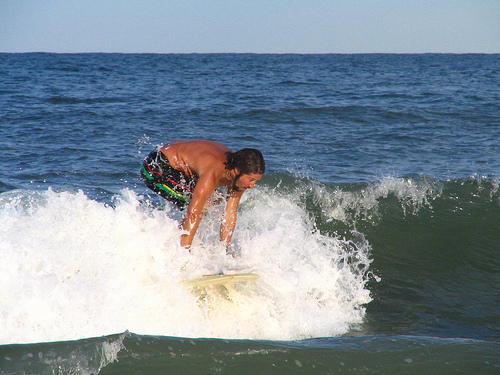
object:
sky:
[1, 2, 499, 55]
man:
[140, 138, 265, 261]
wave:
[0, 169, 496, 375]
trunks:
[141, 149, 196, 212]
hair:
[223, 146, 264, 175]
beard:
[230, 173, 247, 192]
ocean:
[0, 53, 498, 374]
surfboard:
[190, 271, 261, 303]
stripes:
[140, 148, 195, 210]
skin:
[157, 141, 242, 260]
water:
[0, 51, 499, 374]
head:
[223, 147, 264, 194]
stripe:
[142, 166, 188, 202]